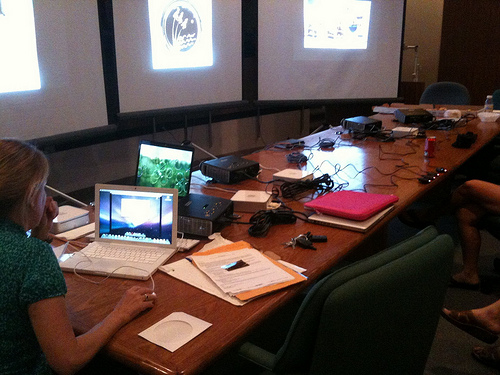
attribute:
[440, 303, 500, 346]
sandal — brown, leather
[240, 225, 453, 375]
chair — green, black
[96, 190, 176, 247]
monitor — illuminated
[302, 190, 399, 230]
book — red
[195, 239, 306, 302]
folder — orange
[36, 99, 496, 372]
table — wood, wooden, cluttered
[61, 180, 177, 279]
laptop — open, white, illuminated